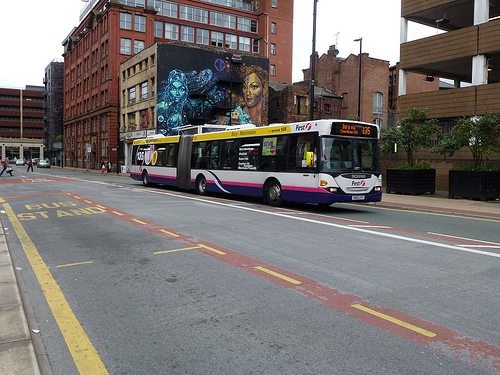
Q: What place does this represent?
A: It represents the highway.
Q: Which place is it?
A: It is a highway.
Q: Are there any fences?
A: No, there are no fences.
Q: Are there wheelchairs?
A: No, there are no wheelchairs.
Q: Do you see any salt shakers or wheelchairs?
A: No, there are no wheelchairs or salt shakers.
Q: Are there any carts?
A: No, there are no carts.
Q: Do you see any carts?
A: No, there are no carts.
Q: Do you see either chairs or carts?
A: No, there are no carts or chairs.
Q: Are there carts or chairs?
A: No, there are no carts or chairs.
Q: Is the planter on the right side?
A: Yes, the planter is on the right of the image.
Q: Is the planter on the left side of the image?
A: No, the planter is on the right of the image.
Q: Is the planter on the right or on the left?
A: The planter is on the right of the image.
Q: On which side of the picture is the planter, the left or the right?
A: The planter is on the right of the image.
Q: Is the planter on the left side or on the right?
A: The planter is on the right of the image.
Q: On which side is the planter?
A: The planter is on the right of the image.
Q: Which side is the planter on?
A: The planter is on the right of the image.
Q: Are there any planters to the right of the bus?
A: Yes, there is a planter to the right of the bus.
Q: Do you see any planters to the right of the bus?
A: Yes, there is a planter to the right of the bus.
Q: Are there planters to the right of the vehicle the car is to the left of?
A: Yes, there is a planter to the right of the bus.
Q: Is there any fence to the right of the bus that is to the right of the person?
A: No, there is a planter to the right of the bus.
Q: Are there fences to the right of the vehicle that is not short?
A: No, there is a planter to the right of the bus.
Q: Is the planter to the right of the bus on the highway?
A: Yes, the planter is to the right of the bus.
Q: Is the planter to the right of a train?
A: No, the planter is to the right of the bus.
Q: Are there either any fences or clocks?
A: No, there are no fences or clocks.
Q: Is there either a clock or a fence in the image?
A: No, there are no fences or clocks.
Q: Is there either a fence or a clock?
A: No, there are no fences or clocks.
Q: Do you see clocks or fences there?
A: No, there are no fences or clocks.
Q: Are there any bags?
A: No, there are no bags.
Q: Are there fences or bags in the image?
A: No, there are no bags or fences.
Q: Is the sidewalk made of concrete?
A: Yes, the sidewalk is made of concrete.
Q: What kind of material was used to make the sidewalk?
A: The sidewalk is made of concrete.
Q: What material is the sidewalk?
A: The sidewalk is made of concrete.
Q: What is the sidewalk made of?
A: The sidewalk is made of concrete.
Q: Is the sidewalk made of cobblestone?
A: No, the sidewalk is made of cement.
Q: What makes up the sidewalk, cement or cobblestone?
A: The sidewalk is made of cement.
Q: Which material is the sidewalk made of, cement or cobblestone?
A: The sidewalk is made of cement.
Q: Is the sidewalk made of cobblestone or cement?
A: The sidewalk is made of cement.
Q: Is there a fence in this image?
A: No, there are no fences.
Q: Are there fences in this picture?
A: No, there are no fences.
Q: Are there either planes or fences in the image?
A: No, there are no fences or planes.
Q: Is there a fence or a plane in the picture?
A: No, there are no fences or airplanes.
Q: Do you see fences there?
A: No, there are no fences.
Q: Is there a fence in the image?
A: No, there are no fences.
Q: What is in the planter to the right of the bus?
A: The tree is in the planter.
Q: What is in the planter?
A: The tree is in the planter.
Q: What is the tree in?
A: The tree is in the planter.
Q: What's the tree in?
A: The tree is in the planter.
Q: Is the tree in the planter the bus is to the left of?
A: Yes, the tree is in the planter.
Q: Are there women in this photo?
A: Yes, there is a woman.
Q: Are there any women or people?
A: Yes, there is a woman.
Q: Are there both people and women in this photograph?
A: Yes, there are both a woman and a person.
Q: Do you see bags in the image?
A: No, there are no bags.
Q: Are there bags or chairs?
A: No, there are no bags or chairs.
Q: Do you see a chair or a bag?
A: No, there are no bags or chairs.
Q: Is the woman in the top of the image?
A: Yes, the woman is in the top of the image.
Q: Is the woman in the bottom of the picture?
A: No, the woman is in the top of the image.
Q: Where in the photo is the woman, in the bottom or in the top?
A: The woman is in the top of the image.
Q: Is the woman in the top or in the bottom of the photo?
A: The woman is in the top of the image.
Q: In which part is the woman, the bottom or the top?
A: The woman is in the top of the image.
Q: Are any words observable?
A: Yes, there are words.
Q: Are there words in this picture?
A: Yes, there are words.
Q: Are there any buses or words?
A: Yes, there are words.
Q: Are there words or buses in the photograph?
A: Yes, there are words.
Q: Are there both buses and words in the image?
A: Yes, there are both words and a bus.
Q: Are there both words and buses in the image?
A: Yes, there are both words and a bus.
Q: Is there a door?
A: Yes, there is a door.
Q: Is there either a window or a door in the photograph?
A: Yes, there is a door.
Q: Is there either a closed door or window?
A: Yes, there is a closed door.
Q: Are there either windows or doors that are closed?
A: Yes, the door is closed.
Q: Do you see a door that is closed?
A: Yes, there is a closed door.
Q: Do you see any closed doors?
A: Yes, there is a closed door.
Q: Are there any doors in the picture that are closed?
A: Yes, there is a door that is closed.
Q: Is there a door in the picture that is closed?
A: Yes, there is a door that is closed.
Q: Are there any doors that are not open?
A: Yes, there is an closed door.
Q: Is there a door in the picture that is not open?
A: Yes, there is an closed door.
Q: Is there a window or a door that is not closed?
A: No, there is a door but it is closed.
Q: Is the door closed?
A: Yes, the door is closed.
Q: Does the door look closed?
A: Yes, the door is closed.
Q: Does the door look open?
A: No, the door is closed.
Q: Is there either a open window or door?
A: No, there is a door but it is closed.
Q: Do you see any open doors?
A: No, there is a door but it is closed.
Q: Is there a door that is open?
A: No, there is a door but it is closed.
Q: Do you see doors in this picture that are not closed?
A: No, there is a door but it is closed.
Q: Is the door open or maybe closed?
A: The door is closed.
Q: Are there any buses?
A: Yes, there is a bus.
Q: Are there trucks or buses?
A: Yes, there is a bus.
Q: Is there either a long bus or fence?
A: Yes, there is a long bus.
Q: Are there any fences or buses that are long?
A: Yes, the bus is long.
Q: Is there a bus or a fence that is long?
A: Yes, the bus is long.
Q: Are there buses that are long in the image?
A: Yes, there is a long bus.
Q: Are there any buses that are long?
A: Yes, there is a bus that is long.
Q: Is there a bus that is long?
A: Yes, there is a bus that is long.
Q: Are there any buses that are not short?
A: Yes, there is a long bus.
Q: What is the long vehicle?
A: The vehicle is a bus.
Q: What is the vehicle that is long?
A: The vehicle is a bus.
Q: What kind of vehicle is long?
A: The vehicle is a bus.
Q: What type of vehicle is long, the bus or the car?
A: The bus is long.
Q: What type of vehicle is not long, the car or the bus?
A: The car is not long.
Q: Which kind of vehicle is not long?
A: The vehicle is a car.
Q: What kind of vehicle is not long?
A: The vehicle is a car.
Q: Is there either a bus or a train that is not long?
A: No, there is a bus but it is long.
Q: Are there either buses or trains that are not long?
A: No, there is a bus but it is long.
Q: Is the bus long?
A: Yes, the bus is long.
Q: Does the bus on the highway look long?
A: Yes, the bus is long.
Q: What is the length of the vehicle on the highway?
A: The bus is long.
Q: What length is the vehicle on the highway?
A: The bus is long.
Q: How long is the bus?
A: The bus is long.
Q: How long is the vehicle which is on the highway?
A: The bus is long.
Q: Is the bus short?
A: No, the bus is long.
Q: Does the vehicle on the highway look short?
A: No, the bus is long.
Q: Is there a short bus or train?
A: No, there is a bus but it is long.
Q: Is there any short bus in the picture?
A: No, there is a bus but it is long.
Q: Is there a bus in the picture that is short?
A: No, there is a bus but it is long.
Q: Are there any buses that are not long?
A: No, there is a bus but it is long.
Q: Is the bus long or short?
A: The bus is long.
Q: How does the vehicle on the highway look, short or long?
A: The bus is long.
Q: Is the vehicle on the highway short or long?
A: The bus is long.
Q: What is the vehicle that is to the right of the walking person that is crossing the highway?
A: The vehicle is a bus.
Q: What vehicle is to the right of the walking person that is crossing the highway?
A: The vehicle is a bus.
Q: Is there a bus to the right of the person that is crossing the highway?
A: Yes, there is a bus to the right of the person.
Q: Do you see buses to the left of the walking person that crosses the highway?
A: No, the bus is to the right of the person.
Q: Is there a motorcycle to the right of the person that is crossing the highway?
A: No, there is a bus to the right of the person.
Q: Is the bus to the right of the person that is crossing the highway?
A: Yes, the bus is to the right of the person.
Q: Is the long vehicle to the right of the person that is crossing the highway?
A: Yes, the bus is to the right of the person.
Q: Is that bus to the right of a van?
A: No, the bus is to the right of the person.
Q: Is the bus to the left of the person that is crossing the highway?
A: No, the bus is to the right of the person.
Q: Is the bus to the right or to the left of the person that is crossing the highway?
A: The bus is to the right of the person.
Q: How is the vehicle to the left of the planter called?
A: The vehicle is a bus.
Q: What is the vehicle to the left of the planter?
A: The vehicle is a bus.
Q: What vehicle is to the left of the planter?
A: The vehicle is a bus.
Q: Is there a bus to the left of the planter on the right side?
A: Yes, there is a bus to the left of the planter.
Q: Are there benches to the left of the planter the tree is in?
A: No, there is a bus to the left of the planter.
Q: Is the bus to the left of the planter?
A: Yes, the bus is to the left of the planter.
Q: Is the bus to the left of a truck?
A: No, the bus is to the left of the planter.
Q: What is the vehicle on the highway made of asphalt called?
A: The vehicle is a bus.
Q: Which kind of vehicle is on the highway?
A: The vehicle is a bus.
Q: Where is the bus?
A: The bus is on the highway.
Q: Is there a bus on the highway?
A: Yes, there is a bus on the highway.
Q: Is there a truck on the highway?
A: No, there is a bus on the highway.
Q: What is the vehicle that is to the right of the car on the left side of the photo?
A: The vehicle is a bus.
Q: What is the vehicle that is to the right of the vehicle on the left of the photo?
A: The vehicle is a bus.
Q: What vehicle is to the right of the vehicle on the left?
A: The vehicle is a bus.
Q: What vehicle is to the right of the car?
A: The vehicle is a bus.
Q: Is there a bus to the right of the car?
A: Yes, there is a bus to the right of the car.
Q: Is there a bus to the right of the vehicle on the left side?
A: Yes, there is a bus to the right of the car.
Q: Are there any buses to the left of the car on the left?
A: No, the bus is to the right of the car.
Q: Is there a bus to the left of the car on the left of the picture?
A: No, the bus is to the right of the car.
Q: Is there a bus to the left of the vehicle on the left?
A: No, the bus is to the right of the car.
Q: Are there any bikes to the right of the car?
A: No, there is a bus to the right of the car.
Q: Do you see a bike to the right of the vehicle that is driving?
A: No, there is a bus to the right of the car.